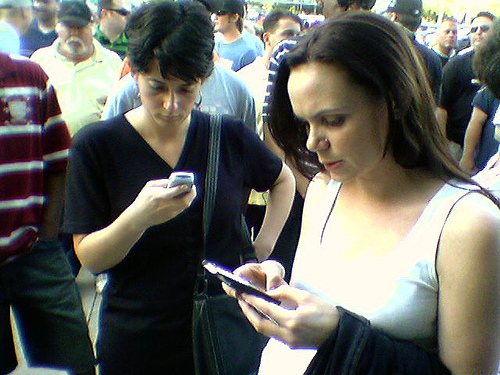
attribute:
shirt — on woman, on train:
[61, 111, 283, 361]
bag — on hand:
[180, 141, 267, 369]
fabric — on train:
[94, 158, 115, 181]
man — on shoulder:
[1, 51, 91, 373]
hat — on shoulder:
[43, 1, 106, 60]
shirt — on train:
[46, 104, 277, 364]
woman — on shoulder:
[68, 1, 278, 373]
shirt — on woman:
[61, 107, 286, 300]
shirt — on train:
[96, 125, 213, 290]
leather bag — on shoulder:
[187, 122, 271, 357]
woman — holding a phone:
[235, 8, 499, 370]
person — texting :
[237, 18, 499, 370]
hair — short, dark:
[119, 0, 215, 84]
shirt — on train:
[67, 120, 267, 281]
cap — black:
[52, 0, 90, 27]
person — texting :
[88, 34, 256, 252]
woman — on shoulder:
[46, 2, 498, 373]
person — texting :
[63, 0, 295, 373]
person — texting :
[213, 16, 450, 370]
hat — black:
[51, 0, 95, 28]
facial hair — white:
[59, 36, 87, 63]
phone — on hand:
[198, 257, 280, 304]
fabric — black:
[80, 171, 289, 373]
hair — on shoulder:
[368, 48, 453, 150]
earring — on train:
[192, 88, 204, 111]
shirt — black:
[63, 114, 281, 332]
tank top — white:
[276, 169, 473, 372]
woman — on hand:
[202, 33, 427, 364]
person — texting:
[284, 31, 484, 366]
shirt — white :
[227, 5, 317, 146]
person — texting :
[208, 20, 493, 373]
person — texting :
[237, 50, 497, 365]